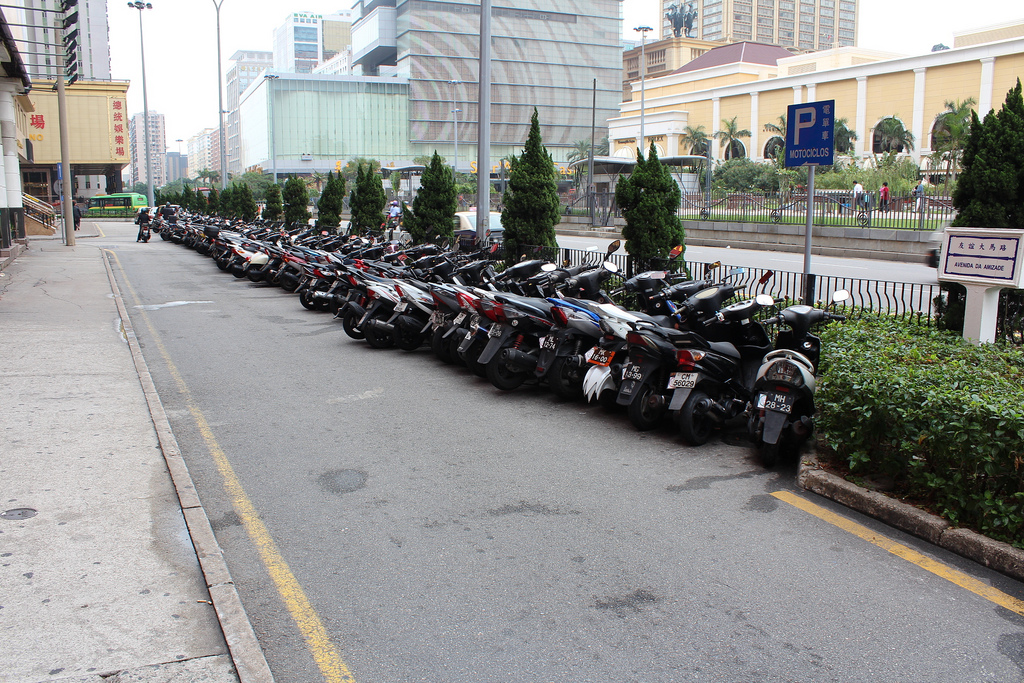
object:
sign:
[786, 99, 835, 166]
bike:
[745, 288, 854, 469]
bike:
[652, 262, 847, 465]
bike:
[588, 243, 854, 478]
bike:
[465, 256, 649, 410]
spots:
[581, 260, 847, 474]